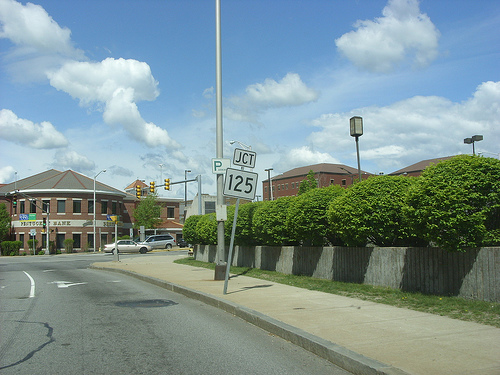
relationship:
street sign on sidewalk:
[217, 146, 261, 297] [102, 257, 499, 374]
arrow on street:
[48, 277, 88, 290] [3, 255, 382, 372]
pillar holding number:
[222, 197, 241, 294] [221, 166, 259, 201]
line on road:
[19, 267, 39, 301] [1, 252, 357, 374]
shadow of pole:
[230, 281, 272, 297] [223, 199, 242, 296]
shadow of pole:
[232, 261, 254, 282] [211, 2, 231, 280]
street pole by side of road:
[216, 199, 242, 298] [1, 252, 357, 374]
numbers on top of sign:
[229, 174, 252, 193] [224, 166, 259, 200]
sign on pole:
[224, 166, 259, 200] [223, 199, 242, 296]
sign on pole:
[233, 147, 258, 168] [223, 199, 242, 296]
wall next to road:
[190, 240, 499, 308] [1, 252, 357, 374]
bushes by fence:
[184, 147, 499, 249] [189, 242, 499, 308]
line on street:
[19, 267, 39, 301] [3, 255, 382, 372]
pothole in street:
[115, 295, 179, 311] [3, 255, 382, 372]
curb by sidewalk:
[102, 264, 295, 374] [102, 257, 499, 374]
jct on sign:
[235, 150, 257, 167] [233, 147, 258, 168]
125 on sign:
[227, 172, 255, 192] [224, 166, 259, 200]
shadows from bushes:
[195, 243, 499, 296] [184, 147, 499, 249]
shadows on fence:
[195, 243, 499, 296] [189, 242, 499, 308]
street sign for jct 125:
[217, 146, 261, 297] [221, 147, 263, 200]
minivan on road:
[138, 233, 177, 250] [1, 252, 357, 374]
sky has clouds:
[2, 2, 495, 159] [7, 5, 186, 172]